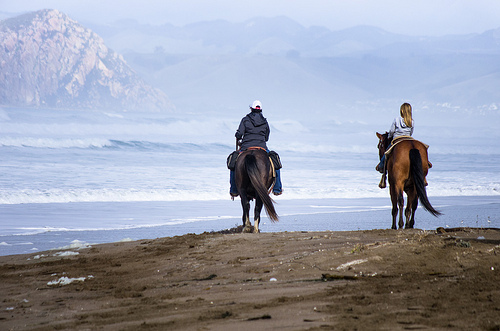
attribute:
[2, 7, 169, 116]
hill — partial, rocky, in distance, muddy, in background, foggy, snow covered, snowy, mountainous, hilly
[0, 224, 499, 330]
shore — the edge, edged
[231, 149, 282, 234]
horse — black, brown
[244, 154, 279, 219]
tail — black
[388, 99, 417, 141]
girl — small, blonde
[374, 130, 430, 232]
horse — brown, the back of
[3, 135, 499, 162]
wave — crashing in distance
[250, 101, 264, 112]
cap — white, partial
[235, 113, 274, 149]
winter jacket — dark blue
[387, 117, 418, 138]
hoody — grey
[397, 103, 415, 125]
hair — blonde, long, blond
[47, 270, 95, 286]
patch of snow — small, white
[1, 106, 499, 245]
water — blue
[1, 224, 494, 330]
dirt — brown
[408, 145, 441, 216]
tail — brown